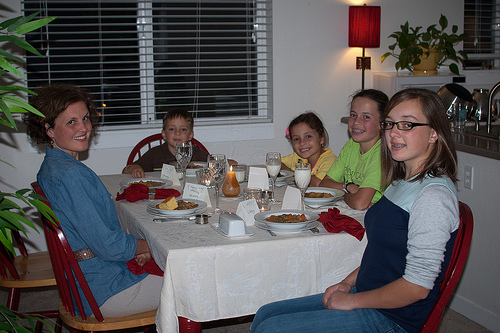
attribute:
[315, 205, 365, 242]
napkin — red, fabric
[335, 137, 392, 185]
tee shirt — green, cotton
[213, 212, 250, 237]
butter plate — white, ceramic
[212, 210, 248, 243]
butter dish — white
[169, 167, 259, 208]
candle — pear shaped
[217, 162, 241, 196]
candle — pear shaped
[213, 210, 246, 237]
butter dish — white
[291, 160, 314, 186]
glass — crystal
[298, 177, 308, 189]
milk — cold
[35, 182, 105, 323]
chair back — wooden, red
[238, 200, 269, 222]
card — white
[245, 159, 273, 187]
card — white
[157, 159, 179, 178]
card — white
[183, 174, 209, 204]
card — white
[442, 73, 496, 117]
pots — silver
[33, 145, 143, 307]
shirt — blue, denim, button down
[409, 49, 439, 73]
pot — yellow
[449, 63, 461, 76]
leaf — green